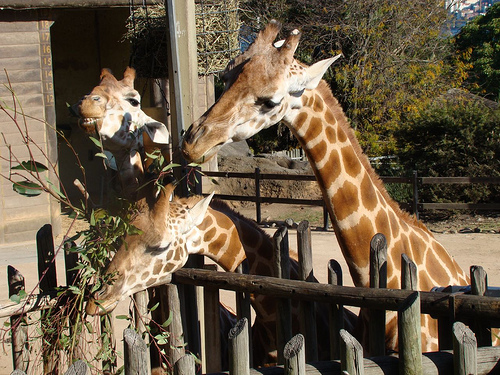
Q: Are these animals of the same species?
A: Yes, all the animals are giraffes.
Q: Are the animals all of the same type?
A: Yes, all the animals are giraffes.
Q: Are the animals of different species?
A: No, all the animals are giraffes.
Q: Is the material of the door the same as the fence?
A: Yes, both the door and the fence are made of wood.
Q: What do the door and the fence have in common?
A: The material, both the door and the fence are wooden.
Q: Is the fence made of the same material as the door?
A: Yes, both the fence and the door are made of wood.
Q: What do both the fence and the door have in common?
A: The material, both the fence and the door are wooden.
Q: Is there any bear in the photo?
A: No, there are no bears.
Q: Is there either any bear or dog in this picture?
A: No, there are no bears or dogs.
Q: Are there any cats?
A: No, there are no cats.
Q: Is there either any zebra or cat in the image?
A: No, there are no cats or zebras.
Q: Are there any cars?
A: No, there are no cars.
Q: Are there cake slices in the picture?
A: No, there are no cake slices.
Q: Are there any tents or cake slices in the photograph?
A: No, there are no cake slices or tents.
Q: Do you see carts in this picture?
A: No, there are no carts.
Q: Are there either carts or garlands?
A: No, there are no carts or garlands.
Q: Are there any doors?
A: Yes, there is a door.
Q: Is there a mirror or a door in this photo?
A: Yes, there is a door.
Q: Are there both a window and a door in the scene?
A: No, there is a door but no windows.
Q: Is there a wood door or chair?
A: Yes, there is a wood door.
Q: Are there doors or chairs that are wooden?
A: Yes, the door is wooden.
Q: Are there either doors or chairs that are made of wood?
A: Yes, the door is made of wood.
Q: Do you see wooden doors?
A: Yes, there is a wood door.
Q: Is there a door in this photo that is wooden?
A: Yes, there is a door that is wooden.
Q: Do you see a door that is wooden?
A: Yes, there is a door that is wooden.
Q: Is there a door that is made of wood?
A: Yes, there is a door that is made of wood.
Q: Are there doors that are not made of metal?
A: Yes, there is a door that is made of wood.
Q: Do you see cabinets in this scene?
A: No, there are no cabinets.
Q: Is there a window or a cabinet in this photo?
A: No, there are no cabinets or windows.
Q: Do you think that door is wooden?
A: Yes, the door is wooden.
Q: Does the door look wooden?
A: Yes, the door is wooden.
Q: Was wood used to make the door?
A: Yes, the door is made of wood.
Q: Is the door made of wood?
A: Yes, the door is made of wood.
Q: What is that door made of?
A: The door is made of wood.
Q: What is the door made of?
A: The door is made of wood.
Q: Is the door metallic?
A: No, the door is wooden.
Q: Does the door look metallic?
A: No, the door is wooden.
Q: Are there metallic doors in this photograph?
A: No, there is a door but it is wooden.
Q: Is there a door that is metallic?
A: No, there is a door but it is wooden.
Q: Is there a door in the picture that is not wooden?
A: No, there is a door but it is wooden.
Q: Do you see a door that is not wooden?
A: No, there is a door but it is wooden.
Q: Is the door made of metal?
A: No, the door is made of wood.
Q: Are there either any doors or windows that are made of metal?
A: No, there is a door but it is made of wood.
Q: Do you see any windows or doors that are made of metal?
A: No, there is a door but it is made of wood.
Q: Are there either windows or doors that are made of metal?
A: No, there is a door but it is made of wood.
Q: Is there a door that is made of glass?
A: No, there is a door but it is made of wood.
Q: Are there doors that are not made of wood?
A: No, there is a door but it is made of wood.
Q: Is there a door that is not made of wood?
A: No, there is a door but it is made of wood.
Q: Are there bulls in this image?
A: No, there are no bulls.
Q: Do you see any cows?
A: No, there are no cows.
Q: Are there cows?
A: No, there are no cows.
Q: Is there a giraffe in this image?
A: Yes, there is a giraffe.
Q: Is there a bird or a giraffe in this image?
A: Yes, there is a giraffe.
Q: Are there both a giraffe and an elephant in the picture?
A: No, there is a giraffe but no elephants.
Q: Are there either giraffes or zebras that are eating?
A: Yes, the giraffe is eating.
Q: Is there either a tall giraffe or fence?
A: Yes, there is a tall giraffe.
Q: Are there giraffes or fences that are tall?
A: Yes, the giraffe is tall.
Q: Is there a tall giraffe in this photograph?
A: Yes, there is a tall giraffe.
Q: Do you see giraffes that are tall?
A: Yes, there is a giraffe that is tall.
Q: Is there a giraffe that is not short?
A: Yes, there is a tall giraffe.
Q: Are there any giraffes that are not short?
A: Yes, there is a tall giraffe.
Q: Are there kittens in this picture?
A: No, there are no kittens.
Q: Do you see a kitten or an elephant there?
A: No, there are no kittens or elephants.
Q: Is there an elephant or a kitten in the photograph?
A: No, there are no kittens or elephants.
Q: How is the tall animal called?
A: The animal is a giraffe.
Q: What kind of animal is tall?
A: The animal is a giraffe.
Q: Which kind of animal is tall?
A: The animal is a giraffe.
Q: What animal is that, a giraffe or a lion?
A: That is a giraffe.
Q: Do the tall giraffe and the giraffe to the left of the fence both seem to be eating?
A: Yes, both the giraffe and the giraffe are eating.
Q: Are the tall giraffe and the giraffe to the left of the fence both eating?
A: Yes, both the giraffe and the giraffe are eating.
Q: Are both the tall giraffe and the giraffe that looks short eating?
A: Yes, both the giraffe and the giraffe are eating.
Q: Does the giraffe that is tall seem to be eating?
A: Yes, the giraffe is eating.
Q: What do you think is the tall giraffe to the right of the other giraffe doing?
A: The giraffe is eating.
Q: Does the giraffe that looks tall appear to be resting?
A: No, the giraffe is eating.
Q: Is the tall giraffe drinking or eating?
A: The giraffe is eating.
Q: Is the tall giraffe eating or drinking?
A: The giraffe is eating.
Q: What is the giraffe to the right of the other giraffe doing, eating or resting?
A: The giraffe is eating.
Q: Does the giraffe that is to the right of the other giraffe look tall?
A: Yes, the giraffe is tall.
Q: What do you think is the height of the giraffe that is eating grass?
A: The giraffe is tall.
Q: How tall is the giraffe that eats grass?
A: The giraffe is tall.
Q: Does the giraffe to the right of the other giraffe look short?
A: No, the giraffe is tall.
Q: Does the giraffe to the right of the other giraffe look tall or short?
A: The giraffe is tall.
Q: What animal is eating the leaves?
A: The giraffe is eating the leaves.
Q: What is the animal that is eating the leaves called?
A: The animal is a giraffe.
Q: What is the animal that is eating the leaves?
A: The animal is a giraffe.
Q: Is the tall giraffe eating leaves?
A: Yes, the giraffe is eating leaves.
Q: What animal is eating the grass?
A: The giraffe is eating the grass.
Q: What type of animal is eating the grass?
A: The animal is a giraffe.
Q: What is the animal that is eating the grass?
A: The animal is a giraffe.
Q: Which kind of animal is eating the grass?
A: The animal is a giraffe.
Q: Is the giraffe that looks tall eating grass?
A: Yes, the giraffe is eating grass.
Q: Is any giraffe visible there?
A: Yes, there is a giraffe.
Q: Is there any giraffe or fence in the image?
A: Yes, there is a giraffe.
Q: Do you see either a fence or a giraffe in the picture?
A: Yes, there is a giraffe.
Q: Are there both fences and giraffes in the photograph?
A: Yes, there are both a giraffe and a fence.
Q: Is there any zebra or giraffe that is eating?
A: Yes, the giraffe is eating.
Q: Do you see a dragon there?
A: No, there are no dragons.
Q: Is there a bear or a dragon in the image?
A: No, there are no dragons or bears.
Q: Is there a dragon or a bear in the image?
A: No, there are no dragons or bears.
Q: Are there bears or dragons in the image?
A: No, there are no dragons or bears.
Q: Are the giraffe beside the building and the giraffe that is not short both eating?
A: Yes, both the giraffe and the giraffe are eating.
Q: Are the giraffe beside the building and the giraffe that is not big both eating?
A: Yes, both the giraffe and the giraffe are eating.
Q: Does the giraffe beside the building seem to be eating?
A: Yes, the giraffe is eating.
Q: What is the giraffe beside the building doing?
A: The giraffe is eating.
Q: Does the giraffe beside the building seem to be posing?
A: No, the giraffe is eating.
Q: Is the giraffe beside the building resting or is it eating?
A: The giraffe is eating.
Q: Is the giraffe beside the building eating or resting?
A: The giraffe is eating.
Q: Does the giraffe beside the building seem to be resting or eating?
A: The giraffe is eating.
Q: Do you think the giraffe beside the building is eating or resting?
A: The giraffe is eating.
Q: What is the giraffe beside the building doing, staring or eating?
A: The giraffe is eating.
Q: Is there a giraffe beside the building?
A: Yes, there is a giraffe beside the building.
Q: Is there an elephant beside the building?
A: No, there is a giraffe beside the building.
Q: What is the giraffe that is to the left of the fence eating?
A: The giraffe is eating leaves.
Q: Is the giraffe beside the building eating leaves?
A: Yes, the giraffe is eating leaves.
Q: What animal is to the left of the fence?
A: The animal is a giraffe.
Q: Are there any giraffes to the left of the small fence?
A: Yes, there is a giraffe to the left of the fence.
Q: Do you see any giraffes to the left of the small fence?
A: Yes, there is a giraffe to the left of the fence.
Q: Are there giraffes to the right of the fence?
A: No, the giraffe is to the left of the fence.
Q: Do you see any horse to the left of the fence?
A: No, there is a giraffe to the left of the fence.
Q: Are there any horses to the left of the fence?
A: No, there is a giraffe to the left of the fence.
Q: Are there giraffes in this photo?
A: Yes, there is a giraffe.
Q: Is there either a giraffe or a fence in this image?
A: Yes, there is a giraffe.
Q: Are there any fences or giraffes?
A: Yes, there is a giraffe.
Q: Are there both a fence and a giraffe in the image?
A: Yes, there are both a giraffe and a fence.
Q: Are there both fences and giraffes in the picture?
A: Yes, there are both a giraffe and a fence.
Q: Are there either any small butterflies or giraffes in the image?
A: Yes, there is a small giraffe.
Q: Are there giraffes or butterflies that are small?
A: Yes, the giraffe is small.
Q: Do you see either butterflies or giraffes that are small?
A: Yes, the giraffe is small.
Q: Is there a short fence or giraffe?
A: Yes, there is a short giraffe.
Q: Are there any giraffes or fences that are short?
A: Yes, the giraffe is short.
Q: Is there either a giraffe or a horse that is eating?
A: Yes, the giraffe is eating.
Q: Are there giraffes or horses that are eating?
A: Yes, the giraffe is eating.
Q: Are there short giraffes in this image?
A: Yes, there is a short giraffe.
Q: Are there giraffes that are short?
A: Yes, there is a giraffe that is short.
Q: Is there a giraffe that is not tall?
A: Yes, there is a short giraffe.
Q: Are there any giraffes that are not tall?
A: Yes, there is a short giraffe.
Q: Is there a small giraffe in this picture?
A: Yes, there is a small giraffe.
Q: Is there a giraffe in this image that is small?
A: Yes, there is a giraffe that is small.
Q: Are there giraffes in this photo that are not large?
A: Yes, there is a small giraffe.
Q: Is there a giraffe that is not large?
A: Yes, there is a small giraffe.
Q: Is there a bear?
A: No, there are no bears.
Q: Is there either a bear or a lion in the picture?
A: No, there are no bears or lions.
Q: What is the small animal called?
A: The animal is a giraffe.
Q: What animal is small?
A: The animal is a giraffe.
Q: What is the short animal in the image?
A: The animal is a giraffe.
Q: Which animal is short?
A: The animal is a giraffe.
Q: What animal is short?
A: The animal is a giraffe.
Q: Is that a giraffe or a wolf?
A: That is a giraffe.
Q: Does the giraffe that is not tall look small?
A: Yes, the giraffe is small.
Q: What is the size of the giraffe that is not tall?
A: The giraffe is small.